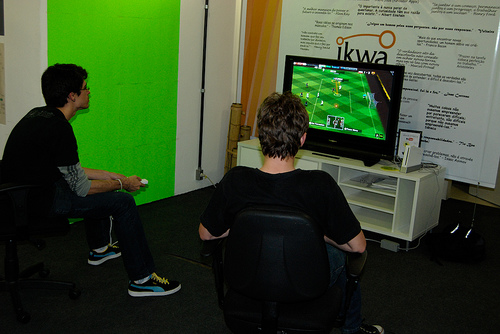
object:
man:
[197, 92, 367, 333]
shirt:
[2, 104, 91, 218]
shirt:
[198, 156, 361, 246]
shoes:
[124, 275, 181, 297]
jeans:
[53, 183, 156, 280]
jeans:
[328, 245, 365, 333]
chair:
[1, 160, 83, 324]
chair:
[199, 205, 368, 333]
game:
[398, 144, 425, 174]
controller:
[139, 177, 149, 186]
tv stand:
[235, 137, 446, 252]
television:
[282, 54, 405, 165]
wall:
[47, 0, 208, 225]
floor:
[0, 181, 499, 332]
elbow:
[80, 179, 90, 197]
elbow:
[196, 224, 212, 241]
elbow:
[351, 245, 366, 255]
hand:
[123, 176, 147, 194]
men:
[1, 62, 184, 297]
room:
[0, 0, 497, 333]